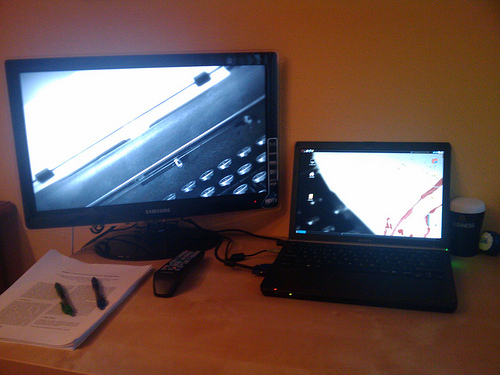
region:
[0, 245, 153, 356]
THERE ARE STACK OF PAPERS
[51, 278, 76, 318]
THERE ARE ABLACK PIN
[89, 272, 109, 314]
THERE ARE ANOTHER BLACK PEN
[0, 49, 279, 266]
THERE ARE A DESK COMPUTION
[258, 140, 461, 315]
THERE ARE ONE LAPTOP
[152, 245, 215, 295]
THERE ARE A BLACK MOUSE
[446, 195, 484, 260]
THERE ARE ONE CUP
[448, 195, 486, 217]
THERE ARE CUP HAVE WHITE LID ON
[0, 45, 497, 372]
THEY ARE SITTING ON A BROWN TABLE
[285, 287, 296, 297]
THERE ARE A GREEN LIGHT ON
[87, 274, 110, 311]
black colored ink pen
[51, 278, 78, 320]
black colored ink pen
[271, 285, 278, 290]
small red colored light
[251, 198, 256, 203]
small red colored light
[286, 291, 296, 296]
small green colored light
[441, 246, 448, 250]
small green colored light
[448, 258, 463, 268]
small green colored light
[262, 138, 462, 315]
black colored laptop computer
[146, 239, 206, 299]
black colored remote control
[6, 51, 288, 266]
black colored computer monitor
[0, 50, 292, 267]
black computer monitor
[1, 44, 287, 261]
SAMSUNG flat screen computer monitor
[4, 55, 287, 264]
computer monitor extending display from laptop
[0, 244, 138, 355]
stack of papers on desk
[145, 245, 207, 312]
large black remote controll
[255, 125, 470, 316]
small black laptop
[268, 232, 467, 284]
laptop keyboard without dedicated numberpad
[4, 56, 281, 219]
computer monitor displaying photo of old fashioned typewriter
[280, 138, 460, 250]
laptop monitor showing edge of old fashioned typewriter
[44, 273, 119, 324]
two ink pens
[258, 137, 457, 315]
black laptop opened on a desk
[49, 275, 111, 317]
two pens on a stack of documents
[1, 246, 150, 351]
stack of tuped documents on a desk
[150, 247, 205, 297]
television remote control on a desk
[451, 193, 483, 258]
a cup of beer on a desk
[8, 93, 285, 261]
monitor with image of typewriter on the screen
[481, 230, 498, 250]
a white and black stress ball on a desk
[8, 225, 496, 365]
a brown office desk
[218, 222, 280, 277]
computer cords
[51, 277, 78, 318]
a black pen on a stack of papers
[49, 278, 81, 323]
A pen on the paper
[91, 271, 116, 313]
A pen on the paper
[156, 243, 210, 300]
A television remote control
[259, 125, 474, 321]
A laptop computer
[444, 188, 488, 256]
A disposable coffee cup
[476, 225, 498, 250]
A stress relief ball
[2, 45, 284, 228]
A computer monitor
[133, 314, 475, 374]
A brown wooden desk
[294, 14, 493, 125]
A yellow wall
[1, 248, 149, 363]
A pile of papers on the desk